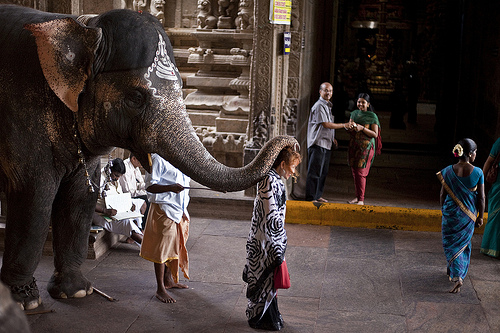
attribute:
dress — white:
[100, 173, 154, 242]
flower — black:
[258, 211, 287, 240]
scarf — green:
[345, 109, 384, 130]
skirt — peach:
[145, 204, 182, 274]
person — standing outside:
[246, 146, 306, 330]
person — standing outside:
[137, 148, 203, 305]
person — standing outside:
[345, 89, 383, 205]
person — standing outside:
[300, 79, 342, 203]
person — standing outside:
[434, 135, 483, 293]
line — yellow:
[280, 198, 437, 230]